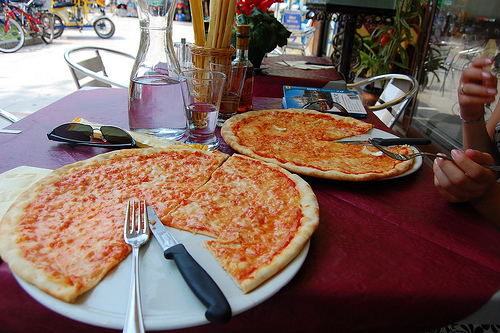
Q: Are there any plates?
A: Yes, there is a plate.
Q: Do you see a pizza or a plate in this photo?
A: Yes, there is a plate.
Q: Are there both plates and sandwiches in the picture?
A: No, there is a plate but no sandwiches.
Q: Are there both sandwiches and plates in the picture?
A: No, there is a plate but no sandwiches.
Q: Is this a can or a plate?
A: This is a plate.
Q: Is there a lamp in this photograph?
A: No, there are no lamps.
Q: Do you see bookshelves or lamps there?
A: No, there are no lamps or bookshelves.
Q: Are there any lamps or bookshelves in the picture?
A: No, there are no lamps or bookshelves.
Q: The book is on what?
A: The book is on the table.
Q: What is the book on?
A: The book is on the table.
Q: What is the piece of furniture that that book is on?
A: The piece of furniture is a table.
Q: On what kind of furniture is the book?
A: The book is on the table.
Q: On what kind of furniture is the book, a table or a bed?
A: The book is on a table.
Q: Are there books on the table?
A: Yes, there is a book on the table.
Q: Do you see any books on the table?
A: Yes, there is a book on the table.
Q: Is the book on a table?
A: Yes, the book is on a table.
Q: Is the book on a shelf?
A: No, the book is on a table.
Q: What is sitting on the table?
A: The book is sitting on the table.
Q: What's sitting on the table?
A: The book is sitting on the table.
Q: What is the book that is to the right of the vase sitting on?
A: The book is sitting on the table.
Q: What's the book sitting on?
A: The book is sitting on the table.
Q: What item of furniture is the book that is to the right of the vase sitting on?
A: The book is sitting on the table.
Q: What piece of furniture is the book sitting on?
A: The book is sitting on the table.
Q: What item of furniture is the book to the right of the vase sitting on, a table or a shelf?
A: The book is sitting on a table.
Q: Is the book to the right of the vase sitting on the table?
A: Yes, the book is sitting on the table.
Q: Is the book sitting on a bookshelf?
A: No, the book is sitting on the table.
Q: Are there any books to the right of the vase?
A: Yes, there is a book to the right of the vase.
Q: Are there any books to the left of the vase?
A: No, the book is to the right of the vase.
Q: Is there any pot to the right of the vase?
A: No, there is a book to the right of the vase.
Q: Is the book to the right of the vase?
A: Yes, the book is to the right of the vase.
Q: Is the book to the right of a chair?
A: No, the book is to the right of the vase.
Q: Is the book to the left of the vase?
A: No, the book is to the right of the vase.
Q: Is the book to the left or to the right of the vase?
A: The book is to the right of the vase.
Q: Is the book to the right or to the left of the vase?
A: The book is to the right of the vase.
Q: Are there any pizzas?
A: Yes, there is a pizza.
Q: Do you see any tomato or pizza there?
A: Yes, there is a pizza.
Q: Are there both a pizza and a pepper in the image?
A: No, there is a pizza but no peppers.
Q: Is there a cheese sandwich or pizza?
A: Yes, there is a cheese pizza.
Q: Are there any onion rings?
A: No, there are no onion rings.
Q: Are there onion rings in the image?
A: No, there are no onion rings.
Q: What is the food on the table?
A: The food is a pizza.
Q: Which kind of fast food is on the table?
A: The food is a pizza.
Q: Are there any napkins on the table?
A: No, there is a pizza on the table.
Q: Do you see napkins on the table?
A: No, there is a pizza on the table.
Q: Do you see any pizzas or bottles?
A: Yes, there is a pizza.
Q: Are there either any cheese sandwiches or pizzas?
A: Yes, there is a cheese pizza.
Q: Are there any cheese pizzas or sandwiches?
A: Yes, there is a cheese pizza.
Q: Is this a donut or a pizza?
A: This is a pizza.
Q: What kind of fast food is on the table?
A: The food is a pizza.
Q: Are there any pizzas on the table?
A: Yes, there is a pizza on the table.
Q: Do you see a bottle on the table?
A: No, there is a pizza on the table.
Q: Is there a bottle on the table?
A: No, there is a pizza on the table.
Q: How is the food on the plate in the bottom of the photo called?
A: The food is a pizza.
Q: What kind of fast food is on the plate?
A: The food is a pizza.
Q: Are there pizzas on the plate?
A: Yes, there is a pizza on the plate.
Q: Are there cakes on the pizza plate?
A: No, there is a pizza on the plate.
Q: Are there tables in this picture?
A: Yes, there is a table.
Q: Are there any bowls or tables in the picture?
A: Yes, there is a table.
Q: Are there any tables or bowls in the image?
A: Yes, there is a table.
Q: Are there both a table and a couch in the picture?
A: No, there is a table but no couches.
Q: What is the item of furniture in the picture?
A: The piece of furniture is a table.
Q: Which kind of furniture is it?
A: The piece of furniture is a table.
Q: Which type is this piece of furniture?
A: This is a table.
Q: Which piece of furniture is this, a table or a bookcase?
A: This is a table.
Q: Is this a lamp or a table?
A: This is a table.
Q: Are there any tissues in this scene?
A: No, there are no tissues.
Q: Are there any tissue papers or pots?
A: No, there are no tissue papers or pots.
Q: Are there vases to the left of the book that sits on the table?
A: Yes, there is a vase to the left of the book.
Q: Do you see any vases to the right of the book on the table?
A: No, the vase is to the left of the book.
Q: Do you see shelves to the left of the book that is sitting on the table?
A: No, there is a vase to the left of the book.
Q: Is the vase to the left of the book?
A: Yes, the vase is to the left of the book.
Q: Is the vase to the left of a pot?
A: No, the vase is to the left of the book.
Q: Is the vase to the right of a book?
A: No, the vase is to the left of a book.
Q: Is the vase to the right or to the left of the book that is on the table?
A: The vase is to the left of the book.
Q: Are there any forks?
A: Yes, there is a fork.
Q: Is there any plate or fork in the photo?
A: Yes, there is a fork.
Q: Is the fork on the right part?
A: No, the fork is on the left of the image.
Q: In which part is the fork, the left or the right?
A: The fork is on the left of the image.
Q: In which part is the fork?
A: The fork is on the left of the image.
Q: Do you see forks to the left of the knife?
A: Yes, there is a fork to the left of the knife.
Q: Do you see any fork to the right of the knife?
A: No, the fork is to the left of the knife.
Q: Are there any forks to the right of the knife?
A: No, the fork is to the left of the knife.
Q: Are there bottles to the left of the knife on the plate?
A: No, there is a fork to the left of the knife.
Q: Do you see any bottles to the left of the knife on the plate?
A: No, there is a fork to the left of the knife.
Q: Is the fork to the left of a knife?
A: Yes, the fork is to the left of a knife.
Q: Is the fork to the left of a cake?
A: No, the fork is to the left of a knife.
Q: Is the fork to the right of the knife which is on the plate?
A: No, the fork is to the left of the knife.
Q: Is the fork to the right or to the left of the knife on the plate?
A: The fork is to the left of the knife.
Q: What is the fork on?
A: The fork is on the plate.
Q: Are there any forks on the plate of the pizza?
A: Yes, there is a fork on the plate.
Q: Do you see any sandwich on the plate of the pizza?
A: No, there is a fork on the plate.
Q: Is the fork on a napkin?
A: No, the fork is on a plate.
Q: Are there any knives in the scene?
A: Yes, there is a knife.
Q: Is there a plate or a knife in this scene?
A: Yes, there is a knife.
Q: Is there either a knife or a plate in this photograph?
A: Yes, there is a knife.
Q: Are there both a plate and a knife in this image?
A: Yes, there are both a knife and a plate.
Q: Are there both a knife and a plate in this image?
A: Yes, there are both a knife and a plate.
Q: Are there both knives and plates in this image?
A: Yes, there are both a knife and plates.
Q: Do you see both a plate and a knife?
A: Yes, there are both a knife and a plate.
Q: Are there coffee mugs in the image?
A: No, there are no coffee mugs.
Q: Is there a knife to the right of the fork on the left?
A: Yes, there is a knife to the right of the fork.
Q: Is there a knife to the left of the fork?
A: No, the knife is to the right of the fork.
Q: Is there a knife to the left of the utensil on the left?
A: No, the knife is to the right of the fork.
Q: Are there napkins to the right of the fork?
A: No, there is a knife to the right of the fork.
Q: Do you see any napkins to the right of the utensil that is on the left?
A: No, there is a knife to the right of the fork.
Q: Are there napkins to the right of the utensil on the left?
A: No, there is a knife to the right of the fork.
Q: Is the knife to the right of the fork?
A: Yes, the knife is to the right of the fork.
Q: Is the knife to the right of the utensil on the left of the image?
A: Yes, the knife is to the right of the fork.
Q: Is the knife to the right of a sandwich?
A: No, the knife is to the right of the fork.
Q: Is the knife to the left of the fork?
A: No, the knife is to the right of the fork.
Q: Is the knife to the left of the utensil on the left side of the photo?
A: No, the knife is to the right of the fork.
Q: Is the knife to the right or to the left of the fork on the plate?
A: The knife is to the right of the fork.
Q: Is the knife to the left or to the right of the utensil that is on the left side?
A: The knife is to the right of the fork.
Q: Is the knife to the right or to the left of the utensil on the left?
A: The knife is to the right of the fork.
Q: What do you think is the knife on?
A: The knife is on the plate.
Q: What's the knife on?
A: The knife is on the plate.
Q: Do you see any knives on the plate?
A: Yes, there is a knife on the plate.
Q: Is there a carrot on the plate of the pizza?
A: No, there is a knife on the plate.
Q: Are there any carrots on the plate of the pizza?
A: No, there is a knife on the plate.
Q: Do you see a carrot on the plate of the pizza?
A: No, there is a knife on the plate.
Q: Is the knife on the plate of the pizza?
A: Yes, the knife is on the plate.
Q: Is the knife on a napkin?
A: No, the knife is on the plate.